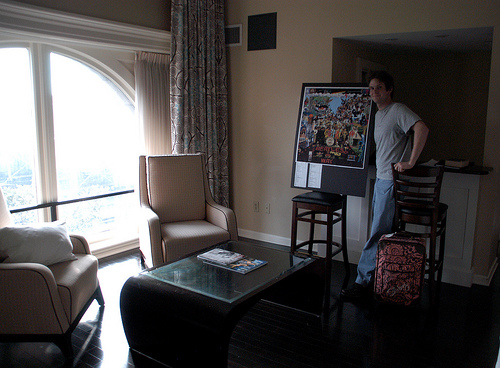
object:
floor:
[0, 235, 498, 367]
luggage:
[372, 231, 426, 304]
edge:
[231, 254, 319, 305]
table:
[122, 237, 328, 367]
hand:
[394, 162, 411, 172]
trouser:
[354, 177, 394, 286]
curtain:
[133, 51, 171, 157]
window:
[0, 44, 140, 245]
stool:
[390, 162, 447, 281]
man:
[339, 73, 428, 300]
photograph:
[297, 83, 373, 168]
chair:
[135, 151, 239, 271]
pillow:
[0, 219, 76, 267]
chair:
[0, 188, 109, 352]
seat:
[292, 192, 342, 204]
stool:
[290, 190, 355, 311]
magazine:
[196, 247, 245, 264]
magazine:
[204, 248, 268, 274]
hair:
[371, 76, 398, 85]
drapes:
[169, 2, 231, 212]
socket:
[253, 201, 259, 212]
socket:
[263, 203, 270, 214]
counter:
[370, 151, 492, 175]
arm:
[205, 200, 237, 232]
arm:
[138, 204, 163, 242]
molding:
[370, 179, 471, 260]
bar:
[362, 152, 494, 288]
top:
[138, 239, 312, 302]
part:
[371, 101, 423, 180]